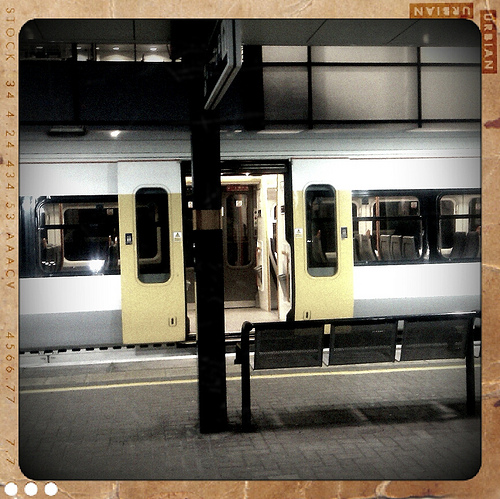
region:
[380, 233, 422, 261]
Railway passenger seat in car.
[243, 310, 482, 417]
Steel bench in railway station.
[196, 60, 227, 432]
Metal beam in railway station.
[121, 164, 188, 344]
Passenger train car door.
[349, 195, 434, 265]
Passenger train car window.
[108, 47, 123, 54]
Building light fixture on ceiling.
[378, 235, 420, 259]
Train car seats for passengers.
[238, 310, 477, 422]
Vacant seat at a rail station.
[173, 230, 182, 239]
Train car door marking symbol.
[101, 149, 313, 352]
opened door to subway train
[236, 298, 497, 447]
bench for waiting on subway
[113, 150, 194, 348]
two tone door of subway car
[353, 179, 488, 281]
window on side of subway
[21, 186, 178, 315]
window on side of subway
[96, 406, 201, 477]
gray tile in subway terminal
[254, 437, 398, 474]
gray tile in subway terminal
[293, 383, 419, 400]
gray tile in subway terminal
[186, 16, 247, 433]
black metal pole with directional sign for subway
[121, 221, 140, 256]
door handle for subway car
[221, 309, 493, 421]
A black, metal bench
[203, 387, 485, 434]
The bench's shadow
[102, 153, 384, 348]
Two open train doors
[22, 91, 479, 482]
A train stopped at the station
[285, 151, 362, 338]
A yellow train door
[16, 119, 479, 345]
A silver train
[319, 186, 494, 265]
Glass train windows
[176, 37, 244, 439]
A black, concrete pole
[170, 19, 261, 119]
A white train stop sign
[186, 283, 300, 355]
The train cabin's floor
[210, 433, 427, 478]
this is a floor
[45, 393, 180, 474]
the floor is made of tiles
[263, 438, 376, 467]
the tiles are rectangular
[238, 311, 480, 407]
this is a bench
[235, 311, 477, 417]
the bench is black in color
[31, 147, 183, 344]
this is a train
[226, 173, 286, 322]
the door is opened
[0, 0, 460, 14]
this is a frame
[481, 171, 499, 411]
the frame is brown in color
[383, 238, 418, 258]
these are chairs inside the train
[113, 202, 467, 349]
the doors are yellow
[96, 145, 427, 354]
the doors are open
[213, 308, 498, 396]
a bench at the station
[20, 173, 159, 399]
windows of a train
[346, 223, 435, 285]
no passengers on the train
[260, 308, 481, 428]
no one sitting on bench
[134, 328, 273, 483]
a black column at the platform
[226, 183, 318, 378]
door of the train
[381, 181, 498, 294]
windows have black frames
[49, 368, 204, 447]
yellow line on platform